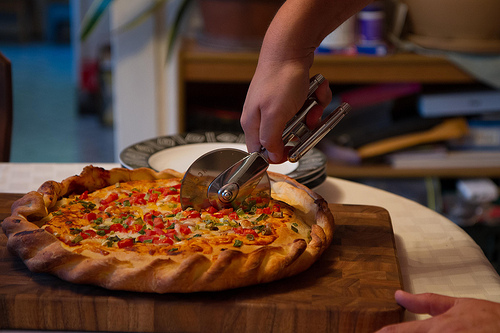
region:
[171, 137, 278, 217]
The pizza cutter blade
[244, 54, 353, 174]
The hand grips the handle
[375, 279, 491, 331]
He holds the cutting board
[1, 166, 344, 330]
A pizza on a cutting board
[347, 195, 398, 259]
The corner of the wooden corner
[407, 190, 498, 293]
The white table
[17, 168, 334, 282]
A supreme pizza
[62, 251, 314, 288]
the twisted pizza crust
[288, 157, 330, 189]
A stack of plates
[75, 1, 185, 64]
Leaves of a plant hanging down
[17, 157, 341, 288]
Pizza for dinner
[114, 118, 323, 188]
Stack of plates besides pizza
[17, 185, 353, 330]
Pizza on a wooden chopping board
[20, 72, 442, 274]
A person cutting a pizza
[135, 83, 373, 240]
Cutter for pizza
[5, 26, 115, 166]
Blurry image of hallway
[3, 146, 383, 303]
Pizza, chopping board and plates on the table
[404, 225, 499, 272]
White table cloth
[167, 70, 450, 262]
Stainless steel pizza cutter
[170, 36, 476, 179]
Cluttered desk in the background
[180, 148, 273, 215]
a pizza cutter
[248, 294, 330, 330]
a brown cutting board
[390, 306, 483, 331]
a persons hand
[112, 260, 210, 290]
crust on the pizza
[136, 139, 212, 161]
a plate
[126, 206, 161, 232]
red peppers on the pizza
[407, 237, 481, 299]
the table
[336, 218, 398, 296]
the cutting board is on the table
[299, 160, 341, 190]
three plates are on the table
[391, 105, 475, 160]
books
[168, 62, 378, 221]
person using pizza slicer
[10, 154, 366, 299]
pizza with breaded crust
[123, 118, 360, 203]
plates seen on background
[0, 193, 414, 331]
cutting board is dark brown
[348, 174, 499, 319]
table is light colored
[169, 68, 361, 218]
pizza slicer made of shiny metal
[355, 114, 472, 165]
cooking utensil in background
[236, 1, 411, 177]
person left hand holding pizza slicer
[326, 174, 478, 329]
cutting board sitting on table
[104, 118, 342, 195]
plates have dark sim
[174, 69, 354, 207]
this is a pizza cutter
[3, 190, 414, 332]
a brown choping board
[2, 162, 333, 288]
this is a pizza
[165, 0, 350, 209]
the person is cutting a piece of pizza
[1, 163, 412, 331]
the pizza is on top of a chopping board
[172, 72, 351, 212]
the cutter is silver in color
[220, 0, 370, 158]
the hand of a man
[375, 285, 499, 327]
the hand of a man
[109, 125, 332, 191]
serving plates for pizza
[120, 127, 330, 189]
the plates are three